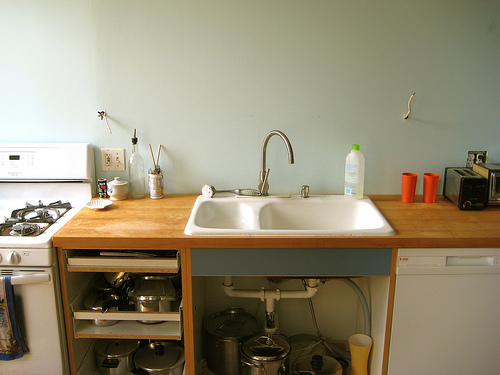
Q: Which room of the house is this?
A: It is a kitchen.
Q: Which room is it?
A: It is a kitchen.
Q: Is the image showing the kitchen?
A: Yes, it is showing the kitchen.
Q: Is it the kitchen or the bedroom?
A: It is the kitchen.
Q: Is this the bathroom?
A: No, it is the kitchen.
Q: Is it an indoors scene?
A: Yes, it is indoors.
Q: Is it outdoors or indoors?
A: It is indoors.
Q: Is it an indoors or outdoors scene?
A: It is indoors.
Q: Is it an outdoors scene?
A: No, it is indoors.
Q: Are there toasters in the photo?
A: Yes, there is a toaster.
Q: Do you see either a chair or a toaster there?
A: Yes, there is a toaster.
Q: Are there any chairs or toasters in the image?
A: Yes, there is a toaster.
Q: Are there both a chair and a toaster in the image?
A: No, there is a toaster but no chairs.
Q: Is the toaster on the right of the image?
A: Yes, the toaster is on the right of the image.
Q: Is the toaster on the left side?
A: No, the toaster is on the right of the image.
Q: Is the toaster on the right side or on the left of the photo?
A: The toaster is on the right of the image.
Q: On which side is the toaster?
A: The toaster is on the right of the image.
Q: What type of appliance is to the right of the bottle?
A: The appliance is a toaster.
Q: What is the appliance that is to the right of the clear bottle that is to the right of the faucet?
A: The appliance is a toaster.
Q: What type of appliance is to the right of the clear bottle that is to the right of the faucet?
A: The appliance is a toaster.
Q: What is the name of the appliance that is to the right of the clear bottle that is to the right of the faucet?
A: The appliance is a toaster.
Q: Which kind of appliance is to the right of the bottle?
A: The appliance is a toaster.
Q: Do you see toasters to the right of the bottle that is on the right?
A: Yes, there is a toaster to the right of the bottle.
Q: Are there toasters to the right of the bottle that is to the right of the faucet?
A: Yes, there is a toaster to the right of the bottle.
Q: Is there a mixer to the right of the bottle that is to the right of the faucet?
A: No, there is a toaster to the right of the bottle.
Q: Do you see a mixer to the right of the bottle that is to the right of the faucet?
A: No, there is a toaster to the right of the bottle.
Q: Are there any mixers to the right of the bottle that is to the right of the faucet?
A: No, there is a toaster to the right of the bottle.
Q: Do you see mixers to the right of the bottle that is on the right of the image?
A: No, there is a toaster to the right of the bottle.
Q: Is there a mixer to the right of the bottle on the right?
A: No, there is a toaster to the right of the bottle.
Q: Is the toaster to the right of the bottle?
A: Yes, the toaster is to the right of the bottle.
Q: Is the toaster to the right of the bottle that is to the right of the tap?
A: Yes, the toaster is to the right of the bottle.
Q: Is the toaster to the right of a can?
A: No, the toaster is to the right of the bottle.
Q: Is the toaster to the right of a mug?
A: No, the toaster is to the right of the cup.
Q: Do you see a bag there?
A: No, there are no bags.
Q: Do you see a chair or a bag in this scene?
A: No, there are no bags or chairs.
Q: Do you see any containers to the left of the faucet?
A: Yes, there is a container to the left of the faucet.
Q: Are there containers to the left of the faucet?
A: Yes, there is a container to the left of the faucet.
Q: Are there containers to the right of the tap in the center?
A: No, the container is to the left of the tap.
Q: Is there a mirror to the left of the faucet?
A: No, there is a container to the left of the faucet.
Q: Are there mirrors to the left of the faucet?
A: No, there is a container to the left of the faucet.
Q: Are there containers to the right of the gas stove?
A: Yes, there is a container to the right of the gas stove.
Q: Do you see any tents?
A: No, there are no tents.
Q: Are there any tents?
A: No, there are no tents.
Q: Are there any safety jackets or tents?
A: No, there are no tents or safety jackets.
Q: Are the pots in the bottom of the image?
A: Yes, the pots are in the bottom of the image.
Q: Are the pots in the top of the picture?
A: No, the pots are in the bottom of the image.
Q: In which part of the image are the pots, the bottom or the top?
A: The pots are in the bottom of the image.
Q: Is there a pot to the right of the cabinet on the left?
A: Yes, there are pots to the right of the cabinet.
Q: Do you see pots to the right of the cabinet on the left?
A: Yes, there are pots to the right of the cabinet.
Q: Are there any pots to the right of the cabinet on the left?
A: Yes, there are pots to the right of the cabinet.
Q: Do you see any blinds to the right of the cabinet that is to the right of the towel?
A: No, there are pots to the right of the cabinet.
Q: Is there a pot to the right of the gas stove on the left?
A: Yes, there are pots to the right of the gas stove.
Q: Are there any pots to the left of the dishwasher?
A: Yes, there are pots to the left of the dishwasher.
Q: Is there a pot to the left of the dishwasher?
A: Yes, there are pots to the left of the dishwasher.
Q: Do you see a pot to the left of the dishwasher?
A: Yes, there are pots to the left of the dishwasher.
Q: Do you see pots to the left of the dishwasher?
A: Yes, there are pots to the left of the dishwasher.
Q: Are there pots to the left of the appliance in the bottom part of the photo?
A: Yes, there are pots to the left of the dishwasher.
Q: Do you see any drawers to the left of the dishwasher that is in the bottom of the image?
A: No, there are pots to the left of the dish washer.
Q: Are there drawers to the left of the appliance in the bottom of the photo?
A: No, there are pots to the left of the dish washer.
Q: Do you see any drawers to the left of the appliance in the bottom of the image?
A: No, there are pots to the left of the dish washer.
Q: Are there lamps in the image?
A: No, there are no lamps.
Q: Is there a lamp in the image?
A: No, there are no lamps.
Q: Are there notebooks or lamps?
A: No, there are no lamps or notebooks.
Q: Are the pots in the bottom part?
A: Yes, the pots are in the bottom of the image.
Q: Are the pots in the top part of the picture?
A: No, the pots are in the bottom of the image.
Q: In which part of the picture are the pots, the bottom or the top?
A: The pots are in the bottom of the image.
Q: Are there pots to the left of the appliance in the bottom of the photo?
A: Yes, there are pots to the left of the dish washer.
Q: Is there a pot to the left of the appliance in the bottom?
A: Yes, there are pots to the left of the dish washer.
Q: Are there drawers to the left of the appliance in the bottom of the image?
A: No, there are pots to the left of the dishwasher.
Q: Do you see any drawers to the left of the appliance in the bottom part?
A: No, there are pots to the left of the dishwasher.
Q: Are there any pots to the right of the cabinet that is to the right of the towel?
A: Yes, there are pots to the right of the cabinet.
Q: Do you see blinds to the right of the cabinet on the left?
A: No, there are pots to the right of the cabinet.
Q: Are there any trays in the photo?
A: No, there are no trays.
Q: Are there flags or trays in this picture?
A: No, there are no trays or flags.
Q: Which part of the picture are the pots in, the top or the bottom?
A: The pots are in the bottom of the image.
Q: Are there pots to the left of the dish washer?
A: Yes, there are pots to the left of the dish washer.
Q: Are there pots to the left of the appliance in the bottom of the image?
A: Yes, there are pots to the left of the dish washer.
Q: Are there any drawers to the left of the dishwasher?
A: No, there are pots to the left of the dishwasher.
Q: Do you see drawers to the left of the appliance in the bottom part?
A: No, there are pots to the left of the dishwasher.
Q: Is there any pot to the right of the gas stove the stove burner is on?
A: Yes, there are pots to the right of the gas stove.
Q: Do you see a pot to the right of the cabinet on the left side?
A: Yes, there are pots to the right of the cabinet.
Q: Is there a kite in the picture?
A: No, there are no kites.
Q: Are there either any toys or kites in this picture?
A: No, there are no kites or toys.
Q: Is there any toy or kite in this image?
A: No, there are no kites or toys.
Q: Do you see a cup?
A: Yes, there is a cup.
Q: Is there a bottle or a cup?
A: Yes, there is a cup.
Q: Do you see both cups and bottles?
A: Yes, there are both a cup and a bottle.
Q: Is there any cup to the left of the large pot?
A: No, the cup is to the right of the pot.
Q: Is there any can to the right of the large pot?
A: No, there is a cup to the right of the pot.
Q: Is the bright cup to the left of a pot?
A: No, the cup is to the right of a pot.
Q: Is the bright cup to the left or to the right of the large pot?
A: The cup is to the right of the pot.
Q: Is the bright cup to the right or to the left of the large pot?
A: The cup is to the right of the pot.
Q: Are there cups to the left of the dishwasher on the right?
A: Yes, there is a cup to the left of the dishwasher.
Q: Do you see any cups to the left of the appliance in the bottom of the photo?
A: Yes, there is a cup to the left of the dishwasher.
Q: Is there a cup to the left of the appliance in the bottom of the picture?
A: Yes, there is a cup to the left of the dishwasher.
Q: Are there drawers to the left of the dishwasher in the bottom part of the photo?
A: No, there is a cup to the left of the dishwasher.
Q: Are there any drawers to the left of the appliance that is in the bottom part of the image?
A: No, there is a cup to the left of the dishwasher.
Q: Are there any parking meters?
A: No, there are no parking meters.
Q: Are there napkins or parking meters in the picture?
A: No, there are no parking meters or napkins.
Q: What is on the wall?
A: The electrical outlet is on the wall.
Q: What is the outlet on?
A: The outlet is on the wall.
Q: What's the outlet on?
A: The outlet is on the wall.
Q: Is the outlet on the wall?
A: Yes, the outlet is on the wall.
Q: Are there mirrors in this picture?
A: No, there are no mirrors.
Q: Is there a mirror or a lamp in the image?
A: No, there are no mirrors or lamps.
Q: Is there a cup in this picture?
A: Yes, there is a cup.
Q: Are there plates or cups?
A: Yes, there is a cup.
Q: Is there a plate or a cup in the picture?
A: Yes, there is a cup.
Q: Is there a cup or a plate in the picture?
A: Yes, there is a cup.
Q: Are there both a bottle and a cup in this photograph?
A: Yes, there are both a cup and a bottle.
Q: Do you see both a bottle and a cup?
A: Yes, there are both a cup and a bottle.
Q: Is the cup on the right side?
A: Yes, the cup is on the right of the image.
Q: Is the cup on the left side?
A: No, the cup is on the right of the image.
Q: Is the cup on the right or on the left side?
A: The cup is on the right of the image.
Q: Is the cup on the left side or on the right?
A: The cup is on the right of the image.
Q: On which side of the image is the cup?
A: The cup is on the right of the image.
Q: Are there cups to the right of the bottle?
A: Yes, there is a cup to the right of the bottle.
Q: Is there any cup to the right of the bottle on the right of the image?
A: Yes, there is a cup to the right of the bottle.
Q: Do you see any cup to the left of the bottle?
A: No, the cup is to the right of the bottle.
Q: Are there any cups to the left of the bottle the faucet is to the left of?
A: No, the cup is to the right of the bottle.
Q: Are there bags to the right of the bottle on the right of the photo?
A: No, there is a cup to the right of the bottle.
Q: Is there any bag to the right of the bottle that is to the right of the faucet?
A: No, there is a cup to the right of the bottle.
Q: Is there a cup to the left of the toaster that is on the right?
A: Yes, there is a cup to the left of the toaster.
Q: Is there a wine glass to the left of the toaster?
A: No, there is a cup to the left of the toaster.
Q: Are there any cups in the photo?
A: Yes, there is a cup.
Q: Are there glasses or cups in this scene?
A: Yes, there is a cup.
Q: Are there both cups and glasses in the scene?
A: No, there is a cup but no glasses.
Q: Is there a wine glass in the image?
A: No, there are no wine glasses.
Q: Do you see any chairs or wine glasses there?
A: No, there are no wine glasses or chairs.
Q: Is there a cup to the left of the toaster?
A: Yes, there is a cup to the left of the toaster.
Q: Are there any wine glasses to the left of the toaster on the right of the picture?
A: No, there is a cup to the left of the toaster.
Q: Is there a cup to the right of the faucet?
A: Yes, there is a cup to the right of the faucet.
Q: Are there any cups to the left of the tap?
A: No, the cup is to the right of the tap.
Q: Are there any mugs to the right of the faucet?
A: No, there is a cup to the right of the faucet.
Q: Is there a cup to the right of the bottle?
A: Yes, there is a cup to the right of the bottle.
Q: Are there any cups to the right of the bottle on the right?
A: Yes, there is a cup to the right of the bottle.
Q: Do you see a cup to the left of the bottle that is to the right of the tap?
A: No, the cup is to the right of the bottle.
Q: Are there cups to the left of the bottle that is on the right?
A: No, the cup is to the right of the bottle.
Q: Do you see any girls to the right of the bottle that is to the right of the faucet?
A: No, there is a cup to the right of the bottle.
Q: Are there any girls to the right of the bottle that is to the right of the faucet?
A: No, there is a cup to the right of the bottle.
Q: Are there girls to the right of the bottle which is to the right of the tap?
A: No, there is a cup to the right of the bottle.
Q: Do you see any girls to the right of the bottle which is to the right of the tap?
A: No, there is a cup to the right of the bottle.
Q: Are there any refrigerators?
A: No, there are no refrigerators.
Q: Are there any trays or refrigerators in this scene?
A: No, there are no refrigerators or trays.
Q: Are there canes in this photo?
A: No, there are no canes.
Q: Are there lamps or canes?
A: No, there are no canes or lamps.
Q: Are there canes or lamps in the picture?
A: No, there are no canes or lamps.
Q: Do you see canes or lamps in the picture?
A: No, there are no canes or lamps.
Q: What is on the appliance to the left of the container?
A: The stove burner is on the gas stove.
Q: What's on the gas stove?
A: The stove burner is on the gas stove.